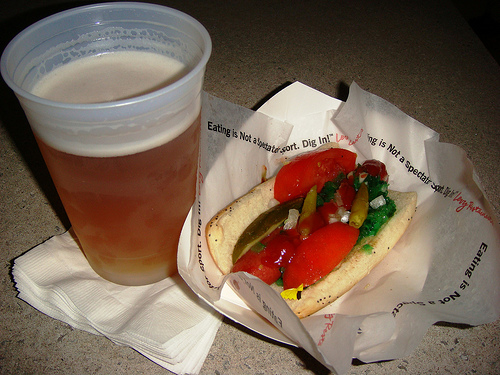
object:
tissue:
[185, 71, 487, 369]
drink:
[0, 10, 216, 280]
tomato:
[269, 147, 358, 201]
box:
[165, 72, 444, 359]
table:
[4, 4, 499, 371]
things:
[6, 5, 493, 366]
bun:
[206, 158, 424, 321]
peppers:
[297, 155, 350, 183]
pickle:
[225, 193, 306, 263]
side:
[207, 134, 299, 330]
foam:
[18, 43, 209, 141]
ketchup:
[251, 221, 303, 270]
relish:
[310, 162, 393, 235]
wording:
[201, 107, 337, 150]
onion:
[284, 195, 388, 228]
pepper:
[270, 222, 374, 286]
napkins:
[10, 207, 225, 364]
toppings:
[235, 159, 396, 281]